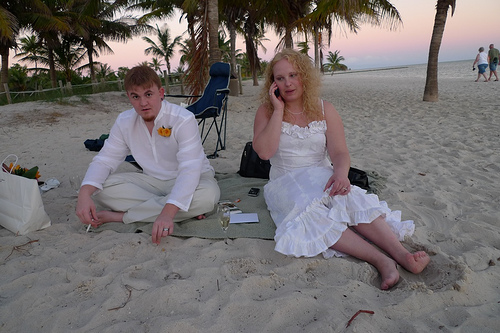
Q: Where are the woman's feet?
A: In the sand.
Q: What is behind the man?
A: A chair.